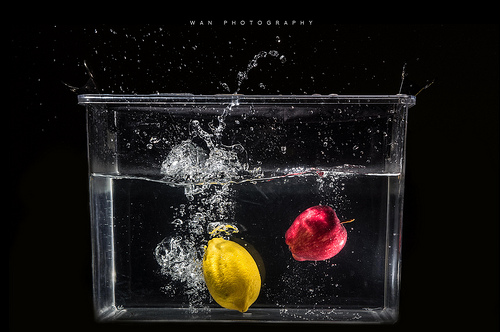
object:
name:
[183, 21, 313, 28]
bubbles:
[172, 218, 185, 226]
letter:
[190, 21, 197, 25]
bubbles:
[280, 144, 292, 156]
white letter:
[289, 18, 297, 27]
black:
[3, 141, 59, 181]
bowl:
[75, 94, 413, 325]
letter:
[238, 19, 246, 27]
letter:
[308, 19, 314, 25]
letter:
[248, 19, 254, 27]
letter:
[206, 20, 214, 27]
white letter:
[197, 20, 205, 27]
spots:
[320, 170, 330, 180]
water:
[234, 51, 286, 93]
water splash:
[146, 51, 289, 180]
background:
[0, 0, 499, 331]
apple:
[283, 205, 357, 261]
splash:
[153, 119, 265, 316]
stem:
[336, 218, 358, 227]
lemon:
[202, 237, 262, 314]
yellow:
[218, 257, 244, 282]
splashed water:
[152, 118, 264, 313]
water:
[92, 120, 402, 321]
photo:
[2, 0, 500, 331]